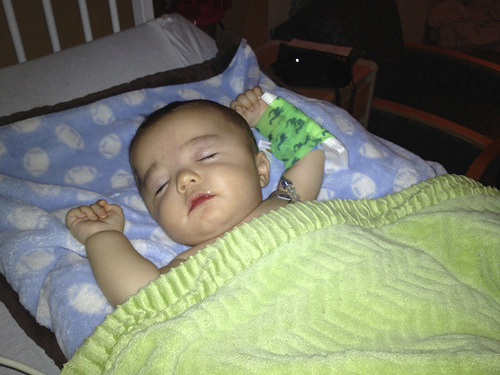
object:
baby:
[65, 84, 325, 310]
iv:
[277, 175, 302, 203]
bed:
[2, 3, 500, 375]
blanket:
[62, 174, 498, 374]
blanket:
[0, 38, 466, 369]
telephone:
[276, 44, 352, 87]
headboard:
[0, 2, 159, 72]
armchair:
[285, 0, 500, 182]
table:
[249, 40, 375, 130]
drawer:
[337, 83, 374, 121]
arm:
[371, 98, 500, 182]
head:
[127, 99, 273, 246]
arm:
[262, 103, 326, 202]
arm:
[84, 230, 191, 311]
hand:
[227, 85, 273, 128]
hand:
[64, 199, 125, 244]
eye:
[196, 148, 222, 163]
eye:
[151, 175, 170, 200]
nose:
[174, 169, 203, 194]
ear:
[257, 150, 271, 187]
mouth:
[183, 191, 217, 215]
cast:
[258, 90, 350, 170]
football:
[98, 132, 121, 160]